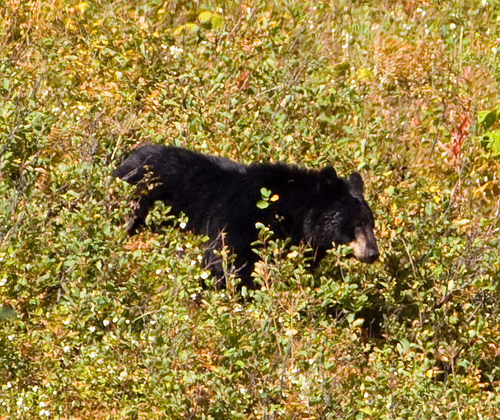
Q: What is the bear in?
A: Grass.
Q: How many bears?
A: 1.